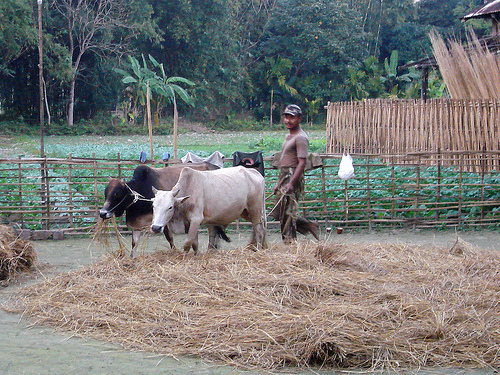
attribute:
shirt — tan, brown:
[275, 133, 308, 166]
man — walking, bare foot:
[274, 102, 322, 243]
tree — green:
[54, 0, 131, 126]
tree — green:
[260, 55, 293, 127]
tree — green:
[174, 0, 229, 124]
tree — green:
[1, 1, 74, 124]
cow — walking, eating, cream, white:
[149, 166, 268, 253]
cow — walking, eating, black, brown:
[98, 165, 208, 257]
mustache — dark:
[284, 121, 293, 127]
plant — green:
[365, 188, 391, 200]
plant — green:
[47, 182, 71, 190]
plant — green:
[77, 147, 105, 154]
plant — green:
[441, 170, 460, 178]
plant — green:
[417, 206, 439, 216]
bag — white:
[337, 151, 355, 181]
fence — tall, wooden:
[0, 149, 498, 225]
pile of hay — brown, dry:
[14, 239, 499, 372]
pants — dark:
[275, 166, 309, 243]